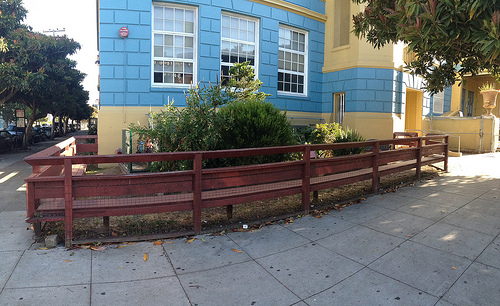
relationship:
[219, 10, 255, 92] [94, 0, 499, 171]
window part of building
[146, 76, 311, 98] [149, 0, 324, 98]
pane of window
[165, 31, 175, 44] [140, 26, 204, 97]
pane of window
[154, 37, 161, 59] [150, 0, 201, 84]
pane part of window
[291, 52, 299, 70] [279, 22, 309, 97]
window pane part of window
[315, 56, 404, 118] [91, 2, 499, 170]
stripe on building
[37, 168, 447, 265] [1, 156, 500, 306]
leaves on sidewalk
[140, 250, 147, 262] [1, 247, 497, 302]
leaf on sidewalk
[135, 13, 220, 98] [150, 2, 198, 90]
pane on window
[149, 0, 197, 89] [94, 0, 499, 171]
window on building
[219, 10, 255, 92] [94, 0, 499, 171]
window on building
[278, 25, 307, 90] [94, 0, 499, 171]
window on building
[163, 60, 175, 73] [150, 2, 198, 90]
pane on window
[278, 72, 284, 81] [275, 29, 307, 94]
pane on window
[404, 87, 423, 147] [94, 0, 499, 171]
doorway on building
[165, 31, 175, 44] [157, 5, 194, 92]
pane on window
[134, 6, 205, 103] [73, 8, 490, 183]
window on building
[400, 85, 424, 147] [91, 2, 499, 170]
doorway into building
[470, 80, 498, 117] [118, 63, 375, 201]
urn for plants